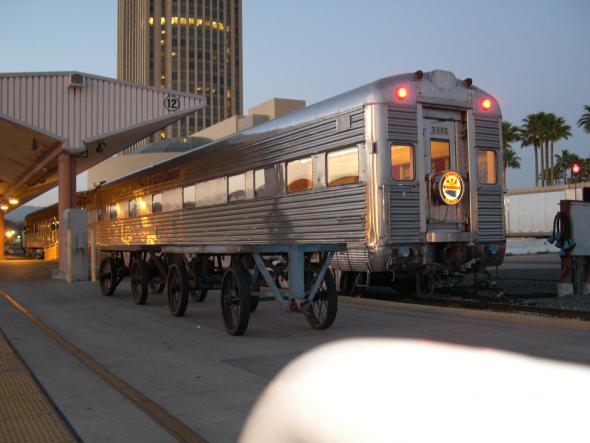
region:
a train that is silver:
[90, 107, 484, 273]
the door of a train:
[405, 102, 475, 230]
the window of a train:
[240, 141, 368, 198]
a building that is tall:
[109, 6, 253, 129]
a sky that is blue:
[264, 18, 345, 66]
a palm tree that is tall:
[524, 109, 568, 182]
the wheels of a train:
[200, 236, 332, 340]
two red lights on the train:
[386, 77, 493, 117]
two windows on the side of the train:
[278, 145, 360, 196]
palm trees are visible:
[520, 109, 568, 188]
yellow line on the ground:
[0, 279, 219, 440]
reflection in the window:
[328, 149, 369, 185]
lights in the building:
[144, 10, 235, 37]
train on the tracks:
[4, 66, 550, 281]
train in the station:
[18, 65, 562, 302]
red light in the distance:
[567, 161, 586, 173]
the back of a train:
[362, 66, 517, 259]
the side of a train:
[88, 141, 396, 249]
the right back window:
[471, 144, 503, 187]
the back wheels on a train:
[221, 236, 333, 351]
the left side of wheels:
[78, 253, 248, 341]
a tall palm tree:
[520, 100, 568, 192]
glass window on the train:
[427, 137, 446, 176]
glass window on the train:
[475, 146, 495, 184]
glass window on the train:
[323, 143, 359, 184]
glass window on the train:
[224, 168, 245, 198]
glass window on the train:
[180, 183, 195, 206]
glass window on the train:
[149, 192, 162, 214]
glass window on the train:
[125, 197, 139, 214]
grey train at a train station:
[23, 62, 511, 305]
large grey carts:
[91, 236, 350, 335]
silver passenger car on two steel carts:
[87, 67, 508, 329]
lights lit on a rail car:
[281, 90, 506, 221]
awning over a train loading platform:
[0, 62, 204, 288]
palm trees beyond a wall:
[506, 100, 588, 198]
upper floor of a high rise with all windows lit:
[134, 4, 238, 36]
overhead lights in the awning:
[0, 188, 26, 220]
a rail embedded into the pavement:
[0, 284, 205, 439]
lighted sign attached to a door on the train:
[422, 104, 473, 232]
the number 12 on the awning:
[160, 88, 189, 115]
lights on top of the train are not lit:
[410, 64, 483, 92]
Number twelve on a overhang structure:
[160, 92, 179, 113]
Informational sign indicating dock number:
[160, 90, 181, 111]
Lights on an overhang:
[0, 196, 19, 212]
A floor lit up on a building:
[150, 13, 235, 32]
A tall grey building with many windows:
[117, 5, 244, 149]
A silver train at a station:
[23, 67, 508, 338]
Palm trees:
[501, 95, 588, 200]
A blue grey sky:
[2, 4, 586, 189]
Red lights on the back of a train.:
[389, 82, 496, 114]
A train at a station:
[5, 59, 552, 428]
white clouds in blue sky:
[261, 18, 291, 46]